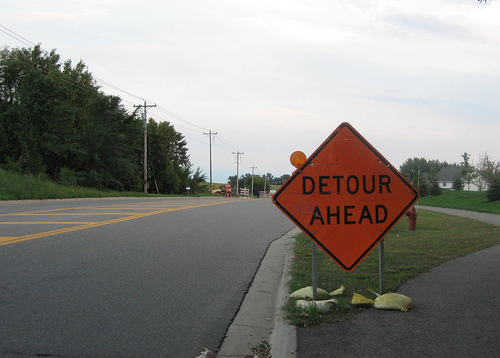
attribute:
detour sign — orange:
[269, 119, 424, 275]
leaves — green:
[22, 100, 101, 140]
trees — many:
[7, 39, 194, 189]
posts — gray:
[303, 240, 392, 304]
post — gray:
[301, 242, 322, 307]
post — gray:
[369, 238, 390, 294]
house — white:
[429, 163, 492, 194]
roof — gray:
[435, 162, 493, 184]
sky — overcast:
[0, 2, 496, 187]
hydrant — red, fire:
[402, 202, 423, 235]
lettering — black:
[301, 167, 396, 231]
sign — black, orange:
[252, 139, 448, 264]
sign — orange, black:
[260, 128, 474, 261]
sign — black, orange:
[284, 148, 413, 276]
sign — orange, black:
[284, 129, 440, 257]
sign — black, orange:
[244, 131, 434, 272]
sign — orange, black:
[267, 129, 414, 250]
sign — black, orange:
[282, 110, 425, 237]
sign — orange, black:
[248, 125, 433, 253]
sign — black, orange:
[238, 115, 387, 251]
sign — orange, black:
[257, 128, 457, 297]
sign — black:
[276, 158, 423, 250]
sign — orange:
[237, 114, 494, 311]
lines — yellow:
[45, 196, 292, 275]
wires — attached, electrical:
[61, 70, 281, 171]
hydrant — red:
[391, 199, 428, 234]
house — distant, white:
[424, 159, 496, 194]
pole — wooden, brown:
[137, 100, 187, 206]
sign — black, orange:
[224, 120, 499, 270]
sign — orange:
[255, 126, 401, 250]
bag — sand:
[341, 265, 440, 327]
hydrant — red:
[379, 202, 456, 256]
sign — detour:
[268, 123, 406, 292]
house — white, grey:
[426, 161, 493, 191]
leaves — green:
[62, 100, 78, 109]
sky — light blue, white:
[7, 7, 498, 163]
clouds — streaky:
[387, 23, 477, 82]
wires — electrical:
[149, 98, 209, 133]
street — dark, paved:
[4, 190, 236, 355]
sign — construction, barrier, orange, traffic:
[271, 117, 426, 318]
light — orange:
[287, 145, 309, 170]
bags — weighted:
[295, 286, 415, 314]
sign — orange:
[269, 120, 422, 269]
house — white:
[437, 162, 486, 192]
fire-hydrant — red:
[403, 200, 422, 235]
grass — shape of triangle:
[351, 177, 498, 250]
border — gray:
[209, 265, 266, 355]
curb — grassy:
[279, 257, 295, 356]